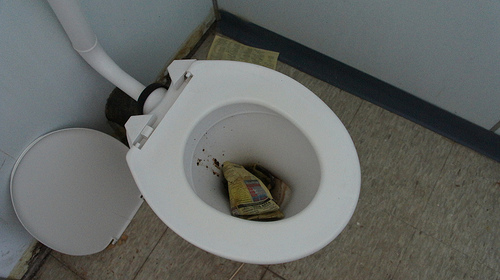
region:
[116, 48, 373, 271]
This is a toilet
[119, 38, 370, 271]
This is a white toilet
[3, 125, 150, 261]
This is a toilet seat cover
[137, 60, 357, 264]
This is a toilet seat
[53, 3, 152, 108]
This is a pipe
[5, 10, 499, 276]
This is a tiled room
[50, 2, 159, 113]
This is a water pipe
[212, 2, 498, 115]
This is a tiled room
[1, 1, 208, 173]
This is a tiled room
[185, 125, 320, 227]
trash in toilet bowl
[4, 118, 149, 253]
broken lid of toilet bowl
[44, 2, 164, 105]
pipe connecting to toilet bowl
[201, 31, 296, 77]
yellow paper on ground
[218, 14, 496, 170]
dark colored base board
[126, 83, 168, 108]
black connector ring on pipe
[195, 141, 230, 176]
stains on the toilet bowl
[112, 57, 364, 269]
white toilet bowl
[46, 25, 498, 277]
beige speckled flooring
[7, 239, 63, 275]
damage to the flooring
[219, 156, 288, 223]
a piece of trash in the toilet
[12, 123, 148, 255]
a white toilet seat cover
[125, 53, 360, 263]
a white toilet seat on a toilet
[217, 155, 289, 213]
the drain of a toilet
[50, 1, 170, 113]
the white pipe of a toilet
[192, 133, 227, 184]
a gross brown spot in the toilet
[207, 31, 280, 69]
a piece of yellow paper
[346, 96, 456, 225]
a tan a white floor tile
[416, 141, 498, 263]
a tan a white floor tile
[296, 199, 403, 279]
a tan a white floor tile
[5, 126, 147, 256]
a tan looking toilet lid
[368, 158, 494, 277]
tan, gray and white bathroom floor tiles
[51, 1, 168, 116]
white pipe leading to toilet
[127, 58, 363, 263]
white toilet with used newsprint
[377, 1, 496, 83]
gray smooth wall in bathroom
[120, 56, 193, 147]
connection of toilet seat to basin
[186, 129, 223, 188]
dirt and stains inside toilet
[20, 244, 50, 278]
missing baseboard along bathroom wall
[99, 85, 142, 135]
exit drain for white toilet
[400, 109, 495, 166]
black baseboard in bathroom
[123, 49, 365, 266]
white toilet seat bowl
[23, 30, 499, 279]
Flooring is speckled tile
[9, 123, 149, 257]
seat lid is leaning on wall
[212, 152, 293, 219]
rolled up paper stuffed in toilet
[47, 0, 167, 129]
white hose connecting to toilet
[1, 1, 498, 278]
the walls are light blue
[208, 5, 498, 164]
baseboards are dark blue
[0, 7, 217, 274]
baseboard is missing from wall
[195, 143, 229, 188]
stains on back of toilet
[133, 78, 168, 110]
black ring on plumbing